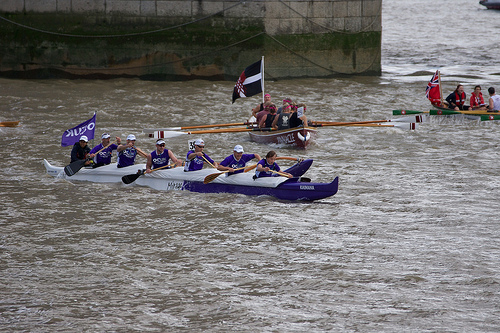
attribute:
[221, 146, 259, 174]
man — rowing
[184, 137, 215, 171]
man — rowing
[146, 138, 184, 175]
man — rowing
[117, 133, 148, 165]
man — rowing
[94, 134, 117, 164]
man — rowing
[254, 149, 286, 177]
woman — rowing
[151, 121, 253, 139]
oar — long, wooden, skinny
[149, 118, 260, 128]
oar — long, wooden, skinny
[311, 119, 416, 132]
oar — long, wooden, skinny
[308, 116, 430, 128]
oar — long, wooden, skinny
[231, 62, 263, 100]
flag — red, white, black